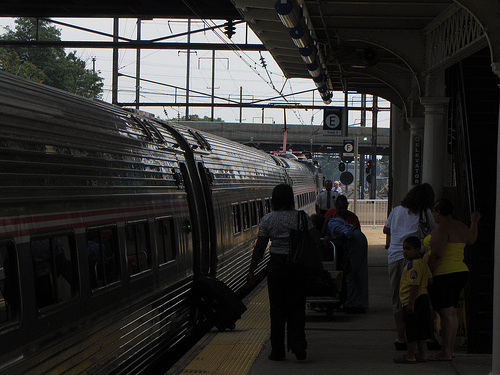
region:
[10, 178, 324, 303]
The passenger windows of the train.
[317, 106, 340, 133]
The hanging train sign with a letter E on it.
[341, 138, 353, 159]
The hanging train sign with the letter F on it.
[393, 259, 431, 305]
The yellow shirt the boy is wearing.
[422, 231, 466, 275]
The yellow shirt the lady is wearing.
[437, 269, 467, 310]
The black shorts the lady is wearing.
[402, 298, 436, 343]
The black shorts the boy is wearing.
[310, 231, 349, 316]
The luggage cart the man is leaning on.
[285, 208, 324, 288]
The black purse the lady is carrying.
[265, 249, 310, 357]
The black pants the lady in the white shirt is wearing.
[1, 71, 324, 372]
rounded silver train with red and white stripes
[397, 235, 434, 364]
young dark skinned boy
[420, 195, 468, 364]
woman wearing a yellow top and black shorts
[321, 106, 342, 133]
the letter E in a white circle on a black sign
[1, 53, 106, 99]
trees behind the train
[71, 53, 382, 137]
utility lines hanging overhead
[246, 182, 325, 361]
woman with dark hair and black pants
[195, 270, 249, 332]
luggage beside the train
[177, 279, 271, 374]
wide yellow line on the pavement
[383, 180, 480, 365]
three people standing on the pavement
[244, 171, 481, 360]
people standing around for trains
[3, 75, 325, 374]
a train parked on the track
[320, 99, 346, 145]
a sign attached to the pole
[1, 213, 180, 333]
the windows on the side of the train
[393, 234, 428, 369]
the little boy standing around with some women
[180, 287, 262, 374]
the yellow line on the platform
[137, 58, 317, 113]
the metal scaffolding above the train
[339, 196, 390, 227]
a fence blocking part of the platform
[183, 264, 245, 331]
a black suitcase sitting outside the train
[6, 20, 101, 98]
a tree with a lot of leaves on it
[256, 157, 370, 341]
people at the platform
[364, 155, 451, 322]
people at the platform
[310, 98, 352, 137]
the letter is E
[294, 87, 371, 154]
the letter is E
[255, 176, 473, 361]
people on the train platform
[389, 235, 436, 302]
the boy in the yellow shirt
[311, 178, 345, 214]
the man with a badge on his shirt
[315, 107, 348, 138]
a sign hanging from overhead the platform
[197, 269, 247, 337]
the black luggage bag in the door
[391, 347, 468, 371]
flip flops on the peoples feet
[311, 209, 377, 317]
the person leaning over on their walker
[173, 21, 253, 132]
the lines above the train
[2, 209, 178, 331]
a row of windows on the train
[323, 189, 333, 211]
the tie on the mans white shirt